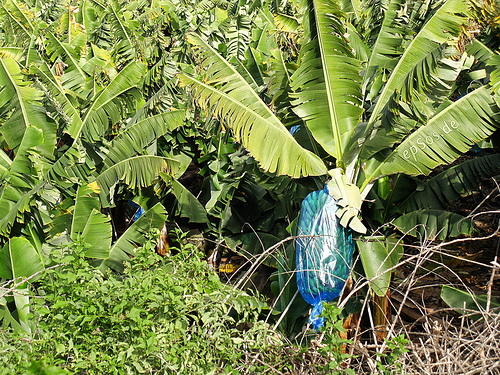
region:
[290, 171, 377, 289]
blue object on the tree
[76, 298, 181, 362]
green grass above the ground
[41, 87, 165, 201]
leaves above the ground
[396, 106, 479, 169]
writing on the tree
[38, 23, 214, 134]
many different leaves on the tree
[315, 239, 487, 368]
branches in the bottom right corner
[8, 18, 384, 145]
daylight photo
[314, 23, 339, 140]
two parts of the tree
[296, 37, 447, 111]
two thick leaves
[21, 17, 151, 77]
leavev in the background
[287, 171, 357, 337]
A blue bag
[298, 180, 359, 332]
a plastic bag on a tree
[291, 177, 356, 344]
A blue bag hanging down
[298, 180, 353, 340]
A bag full of bananas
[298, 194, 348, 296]
A bundlw of bananas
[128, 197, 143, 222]
Another blue bag in the trees.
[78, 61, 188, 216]
The leaves of the banana tree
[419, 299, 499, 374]
branches in the corner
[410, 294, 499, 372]
A bundle of sticks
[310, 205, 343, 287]
The reflection off the bag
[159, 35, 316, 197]
the banana leaf is green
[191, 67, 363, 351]
the banana leaf is green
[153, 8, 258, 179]
the banana leaf is green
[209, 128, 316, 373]
the banana leaf is green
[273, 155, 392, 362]
piece of blue plastic in the plants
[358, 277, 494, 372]
dried twigs and brush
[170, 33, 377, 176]
green healthy leaves of a plant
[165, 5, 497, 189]
a large green plant on the ground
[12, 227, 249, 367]
green leaves on the ground in a bush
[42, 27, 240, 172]
green plants on the ground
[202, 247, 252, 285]
yellow spot on the ground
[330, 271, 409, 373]
brown tree trunk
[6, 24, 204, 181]
dark green vegetation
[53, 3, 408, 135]
field of trees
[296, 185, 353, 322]
turquoise bag holding bananas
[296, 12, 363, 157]
banana tree leaf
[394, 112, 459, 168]
photo company epSos.de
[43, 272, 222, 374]
lush green undergrowth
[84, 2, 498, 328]
green banana trees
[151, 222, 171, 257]
brown trunk of banana tree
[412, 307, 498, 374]
brown dead undergrowth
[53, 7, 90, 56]
dying banana tree palms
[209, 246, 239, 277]
yellow bananas not bagged for shipment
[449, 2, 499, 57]
brown and green banana tree leaves